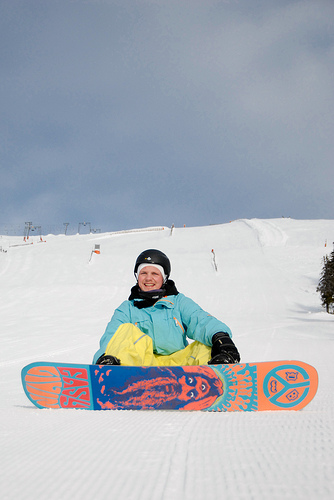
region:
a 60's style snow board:
[22, 359, 318, 412]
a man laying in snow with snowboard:
[18, 249, 318, 409]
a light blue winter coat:
[92, 284, 232, 363]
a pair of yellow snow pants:
[106, 323, 208, 364]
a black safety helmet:
[132, 247, 170, 279]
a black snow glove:
[209, 333, 240, 362]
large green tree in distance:
[319, 252, 333, 311]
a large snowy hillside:
[1, 219, 332, 496]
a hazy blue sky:
[0, 1, 332, 238]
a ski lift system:
[2, 221, 92, 241]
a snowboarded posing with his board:
[12, 243, 325, 416]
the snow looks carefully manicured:
[6, 408, 329, 498]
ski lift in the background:
[3, 212, 107, 243]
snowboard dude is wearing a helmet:
[130, 247, 176, 291]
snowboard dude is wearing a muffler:
[125, 276, 184, 308]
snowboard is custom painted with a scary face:
[15, 355, 324, 415]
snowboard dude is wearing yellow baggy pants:
[101, 317, 213, 366]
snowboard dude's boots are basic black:
[90, 348, 237, 368]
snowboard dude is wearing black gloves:
[209, 329, 242, 364]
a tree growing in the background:
[314, 242, 333, 318]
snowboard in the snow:
[22, 359, 323, 417]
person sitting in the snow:
[78, 239, 246, 367]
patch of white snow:
[116, 450, 129, 464]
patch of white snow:
[209, 458, 227, 477]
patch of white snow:
[277, 461, 298, 478]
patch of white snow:
[108, 475, 124, 491]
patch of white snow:
[132, 446, 144, 463]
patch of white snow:
[271, 439, 291, 459]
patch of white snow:
[66, 469, 87, 495]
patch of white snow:
[146, 438, 164, 452]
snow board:
[16, 350, 321, 430]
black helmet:
[126, 244, 171, 266]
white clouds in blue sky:
[47, 133, 77, 165]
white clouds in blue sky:
[213, 97, 244, 122]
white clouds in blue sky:
[177, 100, 225, 124]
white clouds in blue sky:
[242, 98, 282, 130]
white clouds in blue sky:
[129, 83, 188, 137]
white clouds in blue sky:
[59, 2, 100, 49]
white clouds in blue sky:
[76, 136, 121, 179]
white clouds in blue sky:
[49, 115, 101, 151]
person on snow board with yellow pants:
[39, 230, 280, 420]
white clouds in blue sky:
[44, 45, 92, 94]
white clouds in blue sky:
[139, 29, 189, 64]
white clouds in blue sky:
[210, 108, 272, 178]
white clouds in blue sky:
[179, 25, 213, 56]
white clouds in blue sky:
[133, 75, 167, 106]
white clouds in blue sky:
[54, 91, 91, 135]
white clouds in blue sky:
[248, 32, 282, 69]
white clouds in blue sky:
[119, 77, 164, 114]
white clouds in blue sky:
[22, 54, 63, 119]